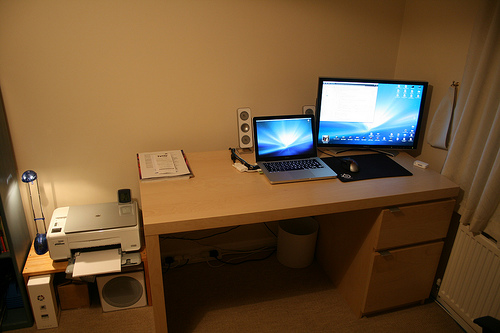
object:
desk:
[133, 133, 463, 332]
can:
[273, 214, 322, 270]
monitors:
[254, 118, 317, 159]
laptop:
[250, 114, 339, 187]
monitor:
[315, 80, 425, 147]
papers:
[135, 149, 193, 183]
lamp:
[18, 168, 50, 257]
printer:
[46, 195, 143, 278]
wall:
[27, 11, 312, 101]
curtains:
[433, 0, 500, 238]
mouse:
[338, 156, 359, 172]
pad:
[317, 153, 412, 184]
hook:
[444, 75, 461, 89]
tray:
[61, 248, 149, 274]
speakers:
[234, 107, 254, 151]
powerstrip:
[160, 246, 227, 270]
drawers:
[369, 199, 459, 253]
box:
[54, 277, 94, 311]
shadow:
[163, 211, 381, 333]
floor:
[177, 268, 343, 333]